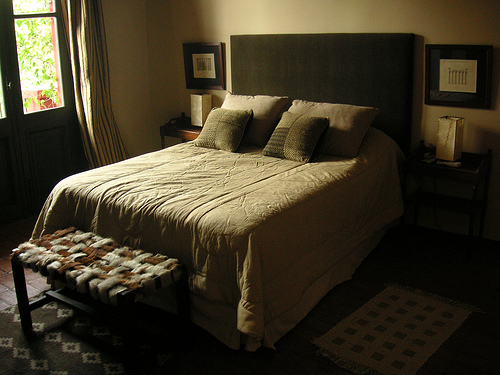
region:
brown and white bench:
[18, 230, 180, 355]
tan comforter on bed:
[41, 141, 393, 333]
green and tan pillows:
[205, 110, 327, 162]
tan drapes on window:
[68, 3, 128, 162]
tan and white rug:
[3, 292, 198, 372]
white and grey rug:
[313, 283, 473, 373]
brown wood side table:
[393, 145, 487, 246]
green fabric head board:
[231, 33, 423, 203]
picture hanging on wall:
[188, 40, 225, 87]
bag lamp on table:
[439, 114, 464, 161]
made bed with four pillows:
[22, 70, 417, 347]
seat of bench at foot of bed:
[20, 222, 180, 303]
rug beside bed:
[291, 274, 482, 374]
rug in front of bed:
[0, 283, 183, 374]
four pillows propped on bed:
[205, 89, 357, 158]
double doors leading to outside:
[5, 0, 95, 218]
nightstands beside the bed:
[155, 113, 493, 268]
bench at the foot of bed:
[11, 225, 192, 362]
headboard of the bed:
[226, 26, 412, 147]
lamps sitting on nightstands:
[186, 88, 467, 168]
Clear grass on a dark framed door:
[0, 3, 67, 181]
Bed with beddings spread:
[46, 69, 416, 337]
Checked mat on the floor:
[313, 277, 480, 374]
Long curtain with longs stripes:
[56, 0, 130, 174]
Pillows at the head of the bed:
[195, 89, 394, 160]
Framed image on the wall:
[418, 38, 495, 111]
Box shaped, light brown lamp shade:
[428, 110, 468, 167]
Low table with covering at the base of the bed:
[1, 223, 208, 363]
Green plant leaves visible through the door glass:
[16, 19, 65, 112]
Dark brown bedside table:
[406, 146, 493, 261]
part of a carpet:
[352, 281, 388, 353]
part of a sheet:
[226, 280, 286, 358]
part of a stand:
[104, 328, 144, 369]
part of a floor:
[362, 280, 406, 335]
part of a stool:
[86, 263, 170, 355]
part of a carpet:
[401, 248, 439, 332]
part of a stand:
[96, 299, 131, 354]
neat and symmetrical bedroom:
[8, 11, 491, 357]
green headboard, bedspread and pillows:
[30, 30, 425, 265]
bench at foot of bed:
[10, 222, 180, 342]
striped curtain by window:
[0, 1, 120, 156]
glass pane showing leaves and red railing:
[5, 11, 60, 116]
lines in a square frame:
[422, 40, 492, 110]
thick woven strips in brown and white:
[12, 225, 172, 297]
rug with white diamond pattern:
[0, 292, 97, 368]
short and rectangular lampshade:
[427, 110, 455, 167]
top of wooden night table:
[153, 125, 199, 146]